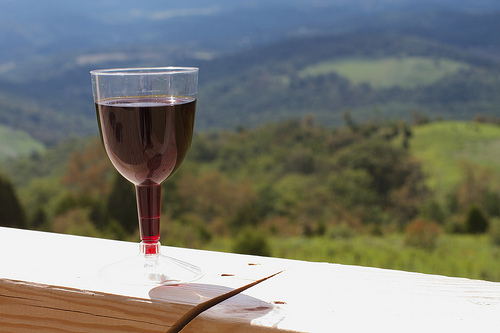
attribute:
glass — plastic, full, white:
[90, 66, 204, 286]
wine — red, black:
[95, 98, 195, 256]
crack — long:
[167, 270, 284, 332]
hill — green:
[0, 121, 499, 235]